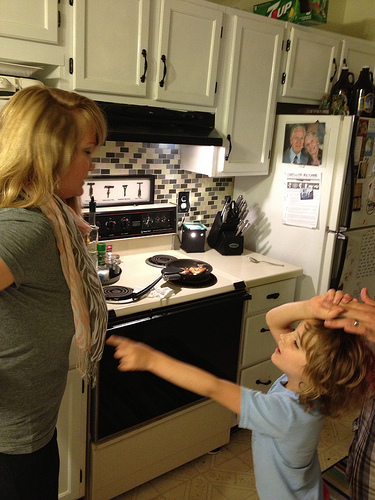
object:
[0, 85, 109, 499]
woman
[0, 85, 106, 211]
hair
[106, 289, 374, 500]
child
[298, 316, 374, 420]
hair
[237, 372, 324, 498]
shirt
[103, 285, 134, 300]
burner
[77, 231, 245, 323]
stove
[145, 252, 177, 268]
burner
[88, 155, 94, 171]
nose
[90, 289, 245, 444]
door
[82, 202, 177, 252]
oven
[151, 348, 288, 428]
arm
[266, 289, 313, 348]
arm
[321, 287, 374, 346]
hand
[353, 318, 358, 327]
ring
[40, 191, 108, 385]
scarf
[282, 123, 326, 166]
couple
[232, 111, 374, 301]
refrigerator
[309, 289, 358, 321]
hand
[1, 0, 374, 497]
kitchen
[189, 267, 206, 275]
food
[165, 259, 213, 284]
frying pan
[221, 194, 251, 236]
knives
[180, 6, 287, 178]
cabinet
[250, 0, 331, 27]
box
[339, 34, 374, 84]
cabinets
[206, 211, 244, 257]
knife box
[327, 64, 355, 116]
bottles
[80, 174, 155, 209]
picture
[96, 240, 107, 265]
spices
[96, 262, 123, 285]
tray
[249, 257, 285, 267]
spoon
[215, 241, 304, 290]
counter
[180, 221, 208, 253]
toaster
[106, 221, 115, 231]
control knobs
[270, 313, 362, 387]
head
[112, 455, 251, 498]
floor